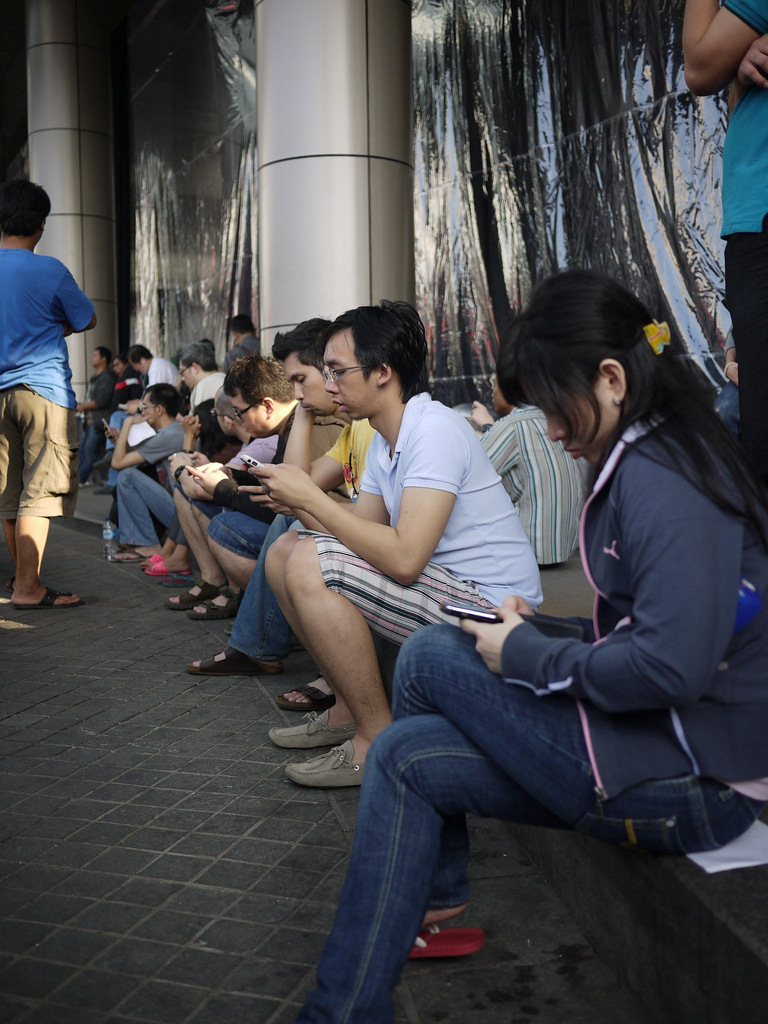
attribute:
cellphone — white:
[439, 597, 499, 626]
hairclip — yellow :
[641, 317, 670, 353]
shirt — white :
[362, 391, 541, 604]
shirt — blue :
[3, 250, 95, 413]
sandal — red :
[390, 917, 484, 964]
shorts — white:
[276, 528, 534, 662]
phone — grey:
[433, 599, 504, 627]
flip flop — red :
[394, 918, 489, 957]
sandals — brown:
[165, 578, 243, 622]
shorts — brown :
[2, 384, 82, 533]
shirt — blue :
[1, 240, 90, 412]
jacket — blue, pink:
[495, 403, 765, 825]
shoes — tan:
[266, 700, 389, 787]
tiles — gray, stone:
[7, 618, 307, 1017]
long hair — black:
[475, 261, 764, 581]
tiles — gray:
[7, 420, 766, 1013]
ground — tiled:
[130, 716, 287, 858]